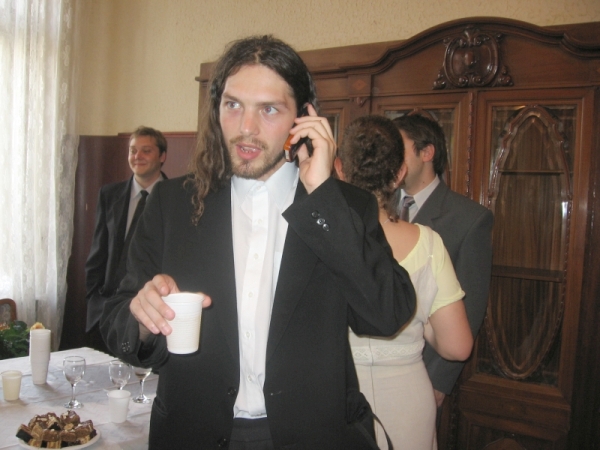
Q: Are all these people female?
A: No, they are both male and female.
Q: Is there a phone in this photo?
A: Yes, there is a phone.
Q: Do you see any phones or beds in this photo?
A: Yes, there is a phone.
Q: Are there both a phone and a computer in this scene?
A: No, there is a phone but no computers.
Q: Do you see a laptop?
A: No, there are no laptops.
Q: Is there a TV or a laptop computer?
A: No, there are no laptops or televisions.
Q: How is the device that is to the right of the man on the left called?
A: The device is a phone.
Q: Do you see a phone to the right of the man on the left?
A: Yes, there is a phone to the right of the man.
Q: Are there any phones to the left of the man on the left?
A: No, the phone is to the right of the man.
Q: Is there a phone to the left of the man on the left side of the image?
A: No, the phone is to the right of the man.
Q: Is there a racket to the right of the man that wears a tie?
A: No, there is a phone to the right of the man.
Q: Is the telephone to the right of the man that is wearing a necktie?
A: Yes, the telephone is to the right of the man.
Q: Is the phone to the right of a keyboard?
A: No, the phone is to the right of the man.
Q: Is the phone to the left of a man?
A: No, the phone is to the right of a man.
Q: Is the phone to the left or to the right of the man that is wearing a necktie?
A: The phone is to the right of the man.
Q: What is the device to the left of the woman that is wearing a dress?
A: The device is a phone.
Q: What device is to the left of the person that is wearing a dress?
A: The device is a phone.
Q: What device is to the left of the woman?
A: The device is a phone.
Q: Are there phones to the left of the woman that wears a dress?
A: Yes, there is a phone to the left of the woman.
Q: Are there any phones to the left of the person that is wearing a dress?
A: Yes, there is a phone to the left of the woman.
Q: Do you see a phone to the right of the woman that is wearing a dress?
A: No, the phone is to the left of the woman.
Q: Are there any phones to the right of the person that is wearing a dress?
A: No, the phone is to the left of the woman.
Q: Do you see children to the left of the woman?
A: No, there is a phone to the left of the woman.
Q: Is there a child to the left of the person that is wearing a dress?
A: No, there is a phone to the left of the woman.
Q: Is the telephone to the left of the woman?
A: Yes, the telephone is to the left of the woman.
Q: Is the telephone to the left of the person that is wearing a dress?
A: Yes, the telephone is to the left of the woman.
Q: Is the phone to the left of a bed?
A: No, the phone is to the left of the woman.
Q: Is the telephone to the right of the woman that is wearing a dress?
A: No, the telephone is to the left of the woman.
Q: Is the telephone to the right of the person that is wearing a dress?
A: No, the telephone is to the left of the woman.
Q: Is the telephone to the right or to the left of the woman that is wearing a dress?
A: The telephone is to the left of the woman.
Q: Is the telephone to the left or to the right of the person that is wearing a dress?
A: The telephone is to the left of the woman.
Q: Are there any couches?
A: No, there are no couches.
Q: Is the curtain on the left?
A: Yes, the curtain is on the left of the image.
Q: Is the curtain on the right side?
A: No, the curtain is on the left of the image.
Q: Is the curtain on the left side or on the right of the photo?
A: The curtain is on the left of the image.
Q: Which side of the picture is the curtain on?
A: The curtain is on the left of the image.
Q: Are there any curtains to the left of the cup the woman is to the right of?
A: Yes, there is a curtain to the left of the cup.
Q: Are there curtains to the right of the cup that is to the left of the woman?
A: No, the curtain is to the left of the cup.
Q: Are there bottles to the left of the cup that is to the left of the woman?
A: No, there is a curtain to the left of the cup.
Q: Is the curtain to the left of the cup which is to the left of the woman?
A: Yes, the curtain is to the left of the cup.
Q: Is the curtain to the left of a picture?
A: No, the curtain is to the left of the cup.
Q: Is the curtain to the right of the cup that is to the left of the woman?
A: No, the curtain is to the left of the cup.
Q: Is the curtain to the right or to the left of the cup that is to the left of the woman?
A: The curtain is to the left of the cup.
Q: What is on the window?
A: The curtain is on the window.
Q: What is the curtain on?
A: The curtain is on the window.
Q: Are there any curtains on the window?
A: Yes, there is a curtain on the window.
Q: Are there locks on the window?
A: No, there is a curtain on the window.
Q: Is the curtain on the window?
A: Yes, the curtain is on the window.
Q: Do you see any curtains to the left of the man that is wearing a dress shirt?
A: Yes, there is a curtain to the left of the man.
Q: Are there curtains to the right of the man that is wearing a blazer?
A: No, the curtain is to the left of the man.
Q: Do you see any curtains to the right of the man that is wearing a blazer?
A: No, the curtain is to the left of the man.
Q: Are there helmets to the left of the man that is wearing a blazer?
A: No, there is a curtain to the left of the man.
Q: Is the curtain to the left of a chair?
A: No, the curtain is to the left of a man.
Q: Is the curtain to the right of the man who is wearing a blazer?
A: No, the curtain is to the left of the man.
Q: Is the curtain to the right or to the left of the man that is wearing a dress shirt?
A: The curtain is to the left of the man.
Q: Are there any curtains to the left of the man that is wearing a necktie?
A: Yes, there is a curtain to the left of the man.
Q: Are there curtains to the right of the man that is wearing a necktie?
A: No, the curtain is to the left of the man.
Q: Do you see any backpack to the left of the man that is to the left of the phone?
A: No, there is a curtain to the left of the man.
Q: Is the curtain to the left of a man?
A: Yes, the curtain is to the left of a man.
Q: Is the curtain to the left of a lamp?
A: No, the curtain is to the left of a man.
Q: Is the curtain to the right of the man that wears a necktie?
A: No, the curtain is to the left of the man.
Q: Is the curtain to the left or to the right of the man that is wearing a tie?
A: The curtain is to the left of the man.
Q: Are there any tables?
A: Yes, there is a table.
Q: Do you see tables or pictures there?
A: Yes, there is a table.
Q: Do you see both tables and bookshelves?
A: No, there is a table but no bookshelves.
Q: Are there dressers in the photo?
A: No, there are no dressers.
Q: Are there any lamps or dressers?
A: No, there are no dressers or lamps.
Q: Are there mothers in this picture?
A: No, there are no mothers.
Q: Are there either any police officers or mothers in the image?
A: No, there are no mothers or police officers.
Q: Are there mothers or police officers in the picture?
A: No, there are no mothers or police officers.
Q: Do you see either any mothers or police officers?
A: No, there are no mothers or police officers.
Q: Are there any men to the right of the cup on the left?
A: Yes, there is a man to the right of the cup.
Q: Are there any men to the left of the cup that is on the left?
A: No, the man is to the right of the cup.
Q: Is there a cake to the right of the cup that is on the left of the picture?
A: No, there is a man to the right of the cup.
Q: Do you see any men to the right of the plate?
A: Yes, there is a man to the right of the plate.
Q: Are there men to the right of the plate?
A: Yes, there is a man to the right of the plate.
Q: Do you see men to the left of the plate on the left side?
A: No, the man is to the right of the plate.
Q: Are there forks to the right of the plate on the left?
A: No, there is a man to the right of the plate.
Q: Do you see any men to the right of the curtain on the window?
A: Yes, there is a man to the right of the curtain.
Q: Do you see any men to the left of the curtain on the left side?
A: No, the man is to the right of the curtain.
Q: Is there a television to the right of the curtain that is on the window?
A: No, there is a man to the right of the curtain.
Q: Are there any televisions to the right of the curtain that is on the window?
A: No, there is a man to the right of the curtain.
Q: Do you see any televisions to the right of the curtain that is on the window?
A: No, there is a man to the right of the curtain.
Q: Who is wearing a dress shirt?
A: The man is wearing a dress shirt.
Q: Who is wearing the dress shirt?
A: The man is wearing a dress shirt.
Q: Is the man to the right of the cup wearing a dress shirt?
A: Yes, the man is wearing a dress shirt.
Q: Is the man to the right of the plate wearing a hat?
A: No, the man is wearing a dress shirt.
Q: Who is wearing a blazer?
A: The man is wearing a blazer.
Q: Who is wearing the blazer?
A: The man is wearing a blazer.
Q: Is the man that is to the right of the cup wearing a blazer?
A: Yes, the man is wearing a blazer.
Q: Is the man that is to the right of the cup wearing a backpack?
A: No, the man is wearing a blazer.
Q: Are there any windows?
A: Yes, there is a window.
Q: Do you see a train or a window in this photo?
A: Yes, there is a window.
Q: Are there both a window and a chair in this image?
A: No, there is a window but no chairs.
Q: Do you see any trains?
A: No, there are no trains.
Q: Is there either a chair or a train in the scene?
A: No, there are no trains or chairs.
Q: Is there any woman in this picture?
A: Yes, there is a woman.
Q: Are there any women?
A: Yes, there is a woman.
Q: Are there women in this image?
A: Yes, there is a woman.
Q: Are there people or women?
A: Yes, there is a woman.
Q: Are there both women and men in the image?
A: Yes, there are both a woman and a man.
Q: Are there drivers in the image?
A: No, there are no drivers.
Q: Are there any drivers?
A: No, there are no drivers.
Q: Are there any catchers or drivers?
A: No, there are no drivers or catchers.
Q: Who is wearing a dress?
A: The woman is wearing a dress.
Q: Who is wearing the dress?
A: The woman is wearing a dress.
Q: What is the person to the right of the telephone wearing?
A: The woman is wearing a dress.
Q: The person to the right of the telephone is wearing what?
A: The woman is wearing a dress.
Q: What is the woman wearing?
A: The woman is wearing a dress.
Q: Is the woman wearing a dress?
A: Yes, the woman is wearing a dress.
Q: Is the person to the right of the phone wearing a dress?
A: Yes, the woman is wearing a dress.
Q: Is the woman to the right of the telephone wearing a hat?
A: No, the woman is wearing a dress.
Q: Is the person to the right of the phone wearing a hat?
A: No, the woman is wearing a dress.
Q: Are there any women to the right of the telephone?
A: Yes, there is a woman to the right of the telephone.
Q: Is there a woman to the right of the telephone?
A: Yes, there is a woman to the right of the telephone.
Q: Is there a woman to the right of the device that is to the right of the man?
A: Yes, there is a woman to the right of the telephone.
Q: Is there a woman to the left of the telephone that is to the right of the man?
A: No, the woman is to the right of the telephone.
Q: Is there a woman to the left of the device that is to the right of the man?
A: No, the woman is to the right of the telephone.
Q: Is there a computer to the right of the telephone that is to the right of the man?
A: No, there is a woman to the right of the telephone.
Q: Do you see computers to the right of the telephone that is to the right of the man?
A: No, there is a woman to the right of the telephone.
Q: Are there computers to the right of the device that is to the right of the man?
A: No, there is a woman to the right of the telephone.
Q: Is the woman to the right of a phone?
A: Yes, the woman is to the right of a phone.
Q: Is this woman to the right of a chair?
A: No, the woman is to the right of a phone.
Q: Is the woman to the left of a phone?
A: No, the woman is to the right of a phone.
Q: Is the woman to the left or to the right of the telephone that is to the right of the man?
A: The woman is to the right of the telephone.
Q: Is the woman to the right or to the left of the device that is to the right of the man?
A: The woman is to the right of the telephone.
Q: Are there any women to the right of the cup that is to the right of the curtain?
A: Yes, there is a woman to the right of the cup.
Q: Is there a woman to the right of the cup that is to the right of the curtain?
A: Yes, there is a woman to the right of the cup.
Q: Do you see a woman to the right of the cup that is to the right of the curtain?
A: Yes, there is a woman to the right of the cup.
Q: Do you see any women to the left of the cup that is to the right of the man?
A: No, the woman is to the right of the cup.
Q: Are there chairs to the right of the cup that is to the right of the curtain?
A: No, there is a woman to the right of the cup.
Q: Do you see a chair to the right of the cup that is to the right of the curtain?
A: No, there is a woman to the right of the cup.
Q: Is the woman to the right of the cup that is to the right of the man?
A: Yes, the woman is to the right of the cup.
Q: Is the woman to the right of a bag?
A: No, the woman is to the right of the cup.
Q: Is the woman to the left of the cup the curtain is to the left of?
A: No, the woman is to the right of the cup.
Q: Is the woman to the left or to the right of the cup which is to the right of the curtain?
A: The woman is to the right of the cup.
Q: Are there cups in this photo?
A: Yes, there is a cup.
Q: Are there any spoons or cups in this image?
A: Yes, there is a cup.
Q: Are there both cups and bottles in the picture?
A: No, there is a cup but no bottles.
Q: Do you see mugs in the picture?
A: No, there are no mugs.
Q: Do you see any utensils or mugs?
A: No, there are no mugs or utensils.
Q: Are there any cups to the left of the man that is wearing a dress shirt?
A: Yes, there is a cup to the left of the man.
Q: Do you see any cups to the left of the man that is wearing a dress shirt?
A: Yes, there is a cup to the left of the man.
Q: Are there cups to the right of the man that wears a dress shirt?
A: No, the cup is to the left of the man.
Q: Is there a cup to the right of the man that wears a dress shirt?
A: No, the cup is to the left of the man.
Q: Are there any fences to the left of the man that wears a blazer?
A: No, there is a cup to the left of the man.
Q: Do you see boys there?
A: No, there are no boys.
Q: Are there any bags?
A: No, there are no bags.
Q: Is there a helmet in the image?
A: No, there are no helmets.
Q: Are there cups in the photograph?
A: Yes, there is a cup.